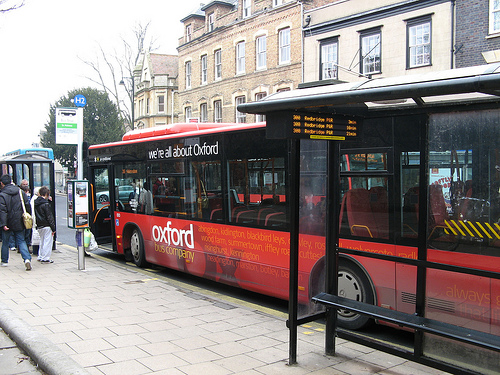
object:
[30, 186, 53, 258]
woman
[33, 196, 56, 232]
jacket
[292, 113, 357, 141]
sign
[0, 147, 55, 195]
bus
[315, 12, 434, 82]
windows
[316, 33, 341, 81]
black frames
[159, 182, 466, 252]
seats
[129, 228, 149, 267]
tire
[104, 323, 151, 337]
tile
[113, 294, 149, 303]
tile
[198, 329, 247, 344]
tile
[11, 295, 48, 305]
tile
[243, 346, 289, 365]
tile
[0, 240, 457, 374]
sidewalk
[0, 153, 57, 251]
bus stop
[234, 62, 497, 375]
bus stop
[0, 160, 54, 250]
black frame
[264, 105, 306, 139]
black frame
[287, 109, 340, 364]
black frame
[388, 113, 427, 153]
black frame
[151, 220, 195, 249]
white words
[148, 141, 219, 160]
message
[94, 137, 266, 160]
black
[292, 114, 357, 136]
words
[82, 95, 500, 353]
bus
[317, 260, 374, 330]
tire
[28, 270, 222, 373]
walkway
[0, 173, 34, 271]
people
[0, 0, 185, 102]
sky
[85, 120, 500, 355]
side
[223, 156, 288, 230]
passenger window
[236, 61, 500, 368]
sheds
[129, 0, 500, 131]
buildings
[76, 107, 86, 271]
pole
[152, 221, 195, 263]
writing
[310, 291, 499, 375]
bench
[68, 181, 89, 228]
sign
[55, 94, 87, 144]
sign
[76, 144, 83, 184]
metal pole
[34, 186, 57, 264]
person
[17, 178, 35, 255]
person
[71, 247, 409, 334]
street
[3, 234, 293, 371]
curb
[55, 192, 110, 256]
road